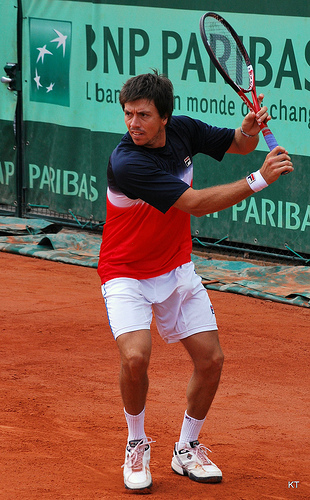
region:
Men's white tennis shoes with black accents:
[120, 436, 223, 493]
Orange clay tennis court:
[0, 248, 309, 498]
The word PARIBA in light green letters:
[229, 195, 308, 232]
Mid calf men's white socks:
[120, 408, 206, 450]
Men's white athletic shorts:
[100, 259, 219, 344]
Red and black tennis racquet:
[197, 10, 273, 134]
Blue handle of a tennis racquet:
[262, 133, 290, 175]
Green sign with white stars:
[27, 15, 73, 108]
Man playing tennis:
[94, 67, 295, 492]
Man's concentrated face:
[121, 97, 168, 146]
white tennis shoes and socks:
[111, 407, 230, 492]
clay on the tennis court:
[255, 368, 296, 422]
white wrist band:
[242, 169, 270, 195]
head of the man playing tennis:
[108, 75, 178, 145]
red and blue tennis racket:
[188, 13, 309, 155]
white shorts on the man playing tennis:
[95, 250, 216, 343]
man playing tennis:
[114, 49, 225, 484]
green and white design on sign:
[29, 18, 71, 102]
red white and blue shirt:
[94, 116, 213, 282]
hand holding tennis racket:
[265, 147, 292, 179]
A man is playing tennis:
[89, 11, 293, 495]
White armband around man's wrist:
[242, 167, 273, 198]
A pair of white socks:
[117, 402, 209, 448]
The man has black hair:
[115, 68, 177, 125]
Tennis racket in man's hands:
[197, 15, 294, 174]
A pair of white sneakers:
[122, 436, 222, 493]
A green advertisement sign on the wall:
[0, 0, 308, 263]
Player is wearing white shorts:
[100, 269, 218, 337]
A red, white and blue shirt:
[95, 112, 233, 286]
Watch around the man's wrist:
[237, 122, 259, 144]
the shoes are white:
[124, 440, 230, 490]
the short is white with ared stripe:
[106, 275, 218, 336]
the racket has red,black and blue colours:
[195, 8, 292, 166]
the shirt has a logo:
[177, 149, 192, 170]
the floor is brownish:
[244, 362, 293, 421]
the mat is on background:
[220, 261, 297, 303]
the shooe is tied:
[122, 430, 153, 466]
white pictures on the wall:
[32, 20, 70, 101]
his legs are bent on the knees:
[122, 295, 231, 476]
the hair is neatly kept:
[125, 73, 175, 119]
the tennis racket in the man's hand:
[190, 9, 297, 177]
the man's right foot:
[118, 432, 158, 496]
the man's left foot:
[167, 437, 227, 486]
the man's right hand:
[259, 145, 293, 194]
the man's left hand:
[242, 90, 273, 135]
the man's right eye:
[123, 110, 132, 117]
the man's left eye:
[138, 110, 149, 117]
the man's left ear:
[158, 109, 169, 125]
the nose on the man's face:
[128, 110, 139, 128]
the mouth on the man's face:
[127, 129, 145, 138]